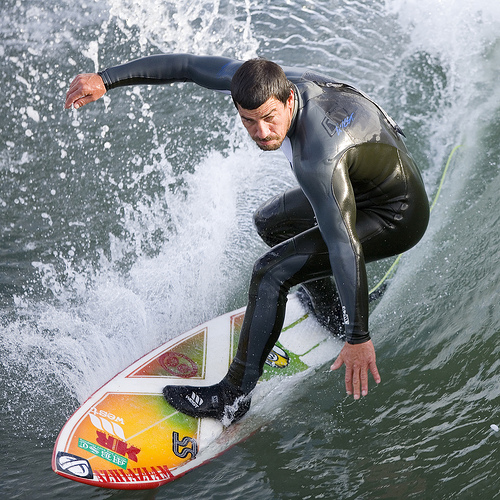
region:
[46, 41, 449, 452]
man surfing in the ocean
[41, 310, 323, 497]
multi colored surf board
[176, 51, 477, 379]
man wearing black wet suit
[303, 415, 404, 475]
green and white ocean waves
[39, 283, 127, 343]
green and white ocean waves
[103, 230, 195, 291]
green and white ocean waves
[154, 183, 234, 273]
green and white ocean waves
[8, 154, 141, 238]
green and white ocean waves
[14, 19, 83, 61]
green and white ocean waves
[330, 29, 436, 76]
green and white ocean waves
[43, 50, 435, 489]
a man on a surfboard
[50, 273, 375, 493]
the surfboard is colorful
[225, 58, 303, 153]
the man has short hair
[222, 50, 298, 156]
the man has dark hair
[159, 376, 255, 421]
the shoe is black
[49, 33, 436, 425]
the man's arms are stretched out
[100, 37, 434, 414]
the man's wet suit is black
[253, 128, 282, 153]
the man has a goatee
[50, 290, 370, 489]
the surfboard is pointy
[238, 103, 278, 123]
the man's eyebrows are dark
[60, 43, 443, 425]
Man is in the foreground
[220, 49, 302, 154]
Man's hair is wet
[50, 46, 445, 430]
Man is wearing a wetsuit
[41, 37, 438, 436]
Man's wetsuit is black and gray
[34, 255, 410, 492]
Man is on a surfboard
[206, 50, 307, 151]
Man's hair is dark colored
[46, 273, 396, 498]
Man's surfboard color is white, yellow, red and green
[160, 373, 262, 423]
Man's shoe is black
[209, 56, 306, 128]
Man's hair is short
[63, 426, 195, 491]
Man's surfboard has red wording near the top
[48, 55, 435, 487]
a man riding a wave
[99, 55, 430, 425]
a man wearing a black wet suit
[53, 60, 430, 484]
a man surfing the wave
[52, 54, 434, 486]
a man keeping his balance on a surfboard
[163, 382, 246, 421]
man wearing a black shoe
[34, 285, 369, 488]
a colorful surfboard on a wave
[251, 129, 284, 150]
man with a goatee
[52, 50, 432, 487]
a surfer on a surfboard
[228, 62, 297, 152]
a man with short brown hair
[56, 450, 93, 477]
a blue and white logo on a surfboard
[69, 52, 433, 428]
The man is wearing a wet suit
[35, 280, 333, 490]
The surf board is white, yellow, green, and red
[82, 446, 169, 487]
Red writing on the surf board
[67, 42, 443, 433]
The wet suit is grey and black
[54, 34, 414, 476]
The man is surfing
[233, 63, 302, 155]
The man has brown hair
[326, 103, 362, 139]
Blue writing on the wet suit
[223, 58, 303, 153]
The man has a beard and mustache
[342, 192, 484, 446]
The water is green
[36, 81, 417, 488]
White spray from the water